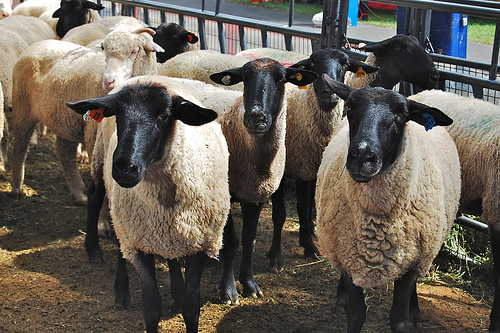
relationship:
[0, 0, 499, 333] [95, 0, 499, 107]
sheep standing in fence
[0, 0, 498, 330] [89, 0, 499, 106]
flock behind fence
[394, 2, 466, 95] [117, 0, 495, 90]
post next fence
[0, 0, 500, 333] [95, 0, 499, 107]
sheep in fence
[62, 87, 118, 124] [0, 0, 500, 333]
ear of sheep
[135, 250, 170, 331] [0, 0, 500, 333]
leg of sheep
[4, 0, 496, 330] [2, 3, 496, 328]
herd in enclosure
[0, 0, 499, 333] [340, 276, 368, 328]
sheep have leg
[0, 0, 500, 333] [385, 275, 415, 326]
sheep have leg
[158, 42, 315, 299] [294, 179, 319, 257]
sheep have leg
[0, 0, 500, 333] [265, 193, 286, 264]
sheep have leg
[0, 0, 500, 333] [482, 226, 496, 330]
sheep have leg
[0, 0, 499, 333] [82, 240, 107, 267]
sheep have hoof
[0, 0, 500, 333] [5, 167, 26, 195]
sheep have hoof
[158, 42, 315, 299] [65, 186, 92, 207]
sheep have hoof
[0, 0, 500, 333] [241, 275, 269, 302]
sheep have hoof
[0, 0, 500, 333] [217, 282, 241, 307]
sheep have hoof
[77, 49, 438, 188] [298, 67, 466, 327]
heads of sheep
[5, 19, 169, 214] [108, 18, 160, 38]
sheep has horns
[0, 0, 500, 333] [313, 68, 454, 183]
sheep has head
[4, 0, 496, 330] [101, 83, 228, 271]
herd has wool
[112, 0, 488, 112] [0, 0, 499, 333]
fence behind sheep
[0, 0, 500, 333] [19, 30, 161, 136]
sheep with fur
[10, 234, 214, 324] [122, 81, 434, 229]
shadow of sheep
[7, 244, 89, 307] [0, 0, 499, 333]
ground for sheep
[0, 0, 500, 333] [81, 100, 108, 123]
sheep have tag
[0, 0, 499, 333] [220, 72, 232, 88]
sheep have tag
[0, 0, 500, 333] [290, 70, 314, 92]
sheep have tag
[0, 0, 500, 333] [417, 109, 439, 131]
sheep have tag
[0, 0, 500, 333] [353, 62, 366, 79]
sheep have tag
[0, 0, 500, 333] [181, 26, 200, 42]
sheep have tag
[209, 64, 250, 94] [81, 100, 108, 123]
ears have tag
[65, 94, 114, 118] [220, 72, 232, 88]
ear have tag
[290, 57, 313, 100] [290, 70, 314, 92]
ears have tag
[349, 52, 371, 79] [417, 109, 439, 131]
ears have tag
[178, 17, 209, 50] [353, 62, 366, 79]
ears have tag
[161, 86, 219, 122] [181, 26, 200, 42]
ears have tag